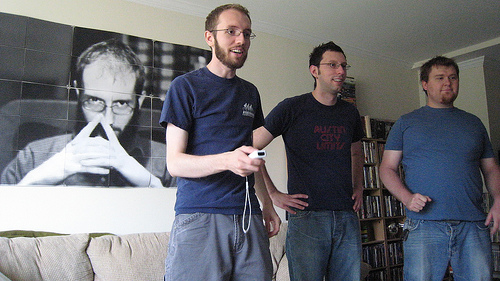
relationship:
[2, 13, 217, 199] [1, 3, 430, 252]
photo on wall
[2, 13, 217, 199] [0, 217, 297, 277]
photo above couch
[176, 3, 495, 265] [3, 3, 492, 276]
three men in room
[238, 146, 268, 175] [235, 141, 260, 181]
control in hand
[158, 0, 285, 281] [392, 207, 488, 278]
man in jeans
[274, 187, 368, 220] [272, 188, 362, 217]
hands on hips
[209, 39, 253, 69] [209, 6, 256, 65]
beard on face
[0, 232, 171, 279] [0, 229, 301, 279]
two pillows on couch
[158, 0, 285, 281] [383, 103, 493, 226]
man in shirt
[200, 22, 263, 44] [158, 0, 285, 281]
glasses on man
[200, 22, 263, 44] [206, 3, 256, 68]
glasses on face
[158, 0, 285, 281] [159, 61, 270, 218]
man wearing t shirt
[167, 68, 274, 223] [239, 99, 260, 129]
shirt has print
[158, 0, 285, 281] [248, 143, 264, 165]
man holding remote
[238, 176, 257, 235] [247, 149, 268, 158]
strap attached to controller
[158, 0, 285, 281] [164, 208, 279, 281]
man wearing blue jeans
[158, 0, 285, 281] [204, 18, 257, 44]
man wearing glasses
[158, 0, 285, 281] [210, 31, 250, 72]
man wearing beard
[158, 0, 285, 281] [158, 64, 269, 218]
man wearing shirt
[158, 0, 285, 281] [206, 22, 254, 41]
man wearing glasses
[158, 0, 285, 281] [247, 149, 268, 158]
man holding controller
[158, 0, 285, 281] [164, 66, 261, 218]
man wearing t-shirt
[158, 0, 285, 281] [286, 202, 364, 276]
man wearing jeans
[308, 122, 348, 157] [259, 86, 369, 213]
red words are on shirt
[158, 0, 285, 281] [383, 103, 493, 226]
man wearing shirt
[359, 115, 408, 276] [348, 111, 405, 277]
books arranged on shelves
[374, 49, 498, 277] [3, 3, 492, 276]
man standing in room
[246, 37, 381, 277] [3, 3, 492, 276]
man standing in room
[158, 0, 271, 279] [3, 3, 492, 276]
man standing in room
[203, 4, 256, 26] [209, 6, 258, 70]
hair on face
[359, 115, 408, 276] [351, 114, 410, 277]
books are on shelves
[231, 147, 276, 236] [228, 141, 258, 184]
controller are on hand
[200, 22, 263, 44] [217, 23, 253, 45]
glasses are on man's eyes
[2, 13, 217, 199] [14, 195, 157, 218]
photo on wall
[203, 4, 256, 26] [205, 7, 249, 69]
hair on head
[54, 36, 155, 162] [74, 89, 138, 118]
man wearing glasses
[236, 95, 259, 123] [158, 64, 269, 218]
white writing on shirt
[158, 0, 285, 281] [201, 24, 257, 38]
man wearing glasses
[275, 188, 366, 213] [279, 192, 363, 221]
hands on hips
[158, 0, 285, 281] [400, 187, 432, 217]
man making fist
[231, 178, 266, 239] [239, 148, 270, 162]
strap attached to controller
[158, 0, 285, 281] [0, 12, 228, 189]
man on photo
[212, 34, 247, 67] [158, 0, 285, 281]
beard on man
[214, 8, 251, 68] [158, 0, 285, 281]
face on man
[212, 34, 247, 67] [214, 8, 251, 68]
beard on face